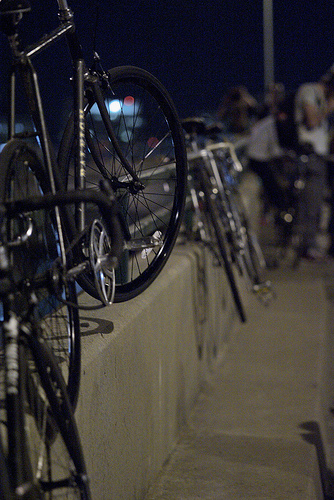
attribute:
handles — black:
[16, 180, 124, 246]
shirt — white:
[297, 78, 332, 147]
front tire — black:
[50, 49, 209, 342]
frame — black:
[3, 18, 84, 153]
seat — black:
[171, 109, 211, 147]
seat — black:
[191, 106, 223, 150]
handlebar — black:
[13, 167, 138, 303]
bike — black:
[1, 4, 213, 387]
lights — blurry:
[87, 84, 153, 142]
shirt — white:
[291, 80, 329, 165]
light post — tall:
[258, 1, 280, 99]